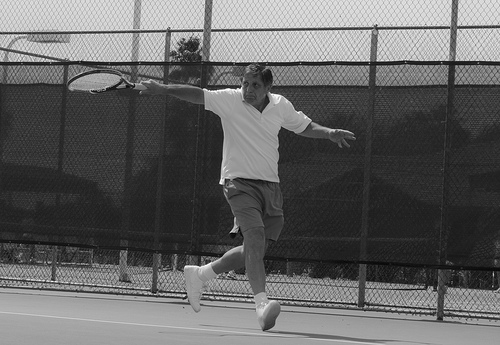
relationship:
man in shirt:
[141, 63, 358, 332] [203, 86, 311, 184]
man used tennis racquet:
[141, 63, 358, 332] [65, 69, 148, 95]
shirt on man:
[203, 86, 311, 184] [141, 63, 358, 332]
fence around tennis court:
[0, 0, 498, 321] [0, 286, 499, 343]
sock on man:
[199, 263, 217, 283] [141, 63, 358, 332]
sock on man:
[252, 290, 270, 307] [141, 63, 358, 332]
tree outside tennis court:
[163, 35, 213, 208] [0, 286, 499, 343]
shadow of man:
[265, 328, 416, 344] [141, 63, 358, 332]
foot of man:
[183, 264, 209, 312] [141, 63, 358, 332]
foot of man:
[254, 298, 282, 332] [141, 63, 358, 332]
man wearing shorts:
[141, 63, 358, 332] [222, 177, 286, 243]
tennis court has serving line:
[0, 286, 499, 343] [1, 309, 385, 344]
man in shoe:
[141, 63, 358, 332] [181, 264, 207, 313]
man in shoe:
[141, 63, 358, 332] [257, 299, 283, 330]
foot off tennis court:
[183, 264, 209, 312] [0, 286, 499, 343]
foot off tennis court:
[254, 298, 282, 332] [0, 286, 499, 343]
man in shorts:
[141, 63, 358, 332] [222, 177, 286, 243]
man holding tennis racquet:
[141, 63, 358, 332] [65, 69, 148, 95]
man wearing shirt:
[141, 63, 358, 332] [203, 86, 311, 184]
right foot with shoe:
[254, 298, 282, 332] [257, 299, 283, 330]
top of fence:
[0, 23, 499, 35] [0, 0, 498, 321]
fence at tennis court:
[0, 0, 498, 321] [0, 286, 499, 343]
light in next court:
[2, 29, 70, 86] [0, 246, 499, 311]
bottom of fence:
[0, 273, 498, 321] [0, 0, 498, 321]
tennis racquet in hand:
[65, 69, 148, 95] [138, 78, 165, 97]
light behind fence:
[2, 29, 70, 86] [0, 0, 498, 321]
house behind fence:
[196, 141, 497, 272] [0, 0, 498, 321]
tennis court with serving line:
[0, 286, 499, 343] [1, 309, 385, 344]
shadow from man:
[265, 328, 416, 344] [141, 63, 358, 332]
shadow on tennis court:
[265, 328, 416, 344] [0, 286, 499, 343]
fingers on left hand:
[336, 127, 358, 152] [328, 125, 358, 152]